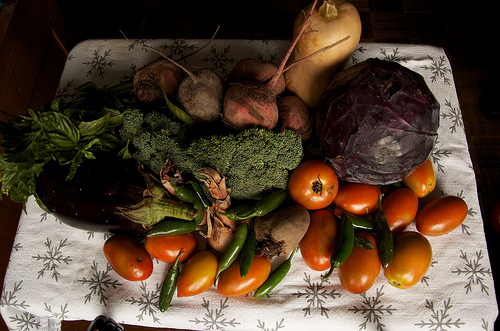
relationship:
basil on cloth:
[39, 109, 81, 152] [4, 38, 497, 328]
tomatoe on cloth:
[414, 190, 470, 236] [4, 38, 497, 328]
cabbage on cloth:
[317, 55, 443, 184] [4, 38, 497, 328]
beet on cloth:
[223, 7, 316, 128] [4, 38, 497, 328]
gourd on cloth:
[283, 0, 362, 114] [4, 38, 497, 328]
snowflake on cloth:
[30, 236, 72, 286] [4, 38, 497, 328]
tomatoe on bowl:
[414, 190, 470, 236] [30, 152, 144, 235]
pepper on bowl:
[317, 211, 352, 282] [30, 152, 144, 235]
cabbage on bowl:
[317, 55, 443, 184] [30, 152, 144, 235]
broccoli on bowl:
[188, 126, 304, 201] [30, 152, 144, 235]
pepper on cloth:
[317, 211, 352, 282] [4, 38, 497, 328]